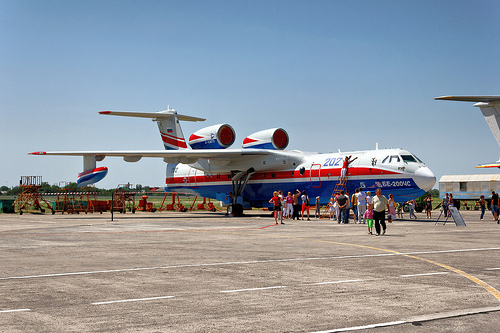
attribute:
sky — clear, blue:
[22, 70, 112, 102]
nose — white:
[412, 165, 434, 192]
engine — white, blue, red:
[188, 124, 237, 150]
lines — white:
[72, 212, 417, 332]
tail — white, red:
[94, 105, 209, 154]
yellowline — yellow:
[304, 236, 499, 327]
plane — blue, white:
[43, 87, 455, 227]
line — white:
[223, 285, 283, 295]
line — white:
[313, 275, 370, 287]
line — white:
[400, 267, 447, 277]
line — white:
[91, 292, 171, 304]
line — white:
[0, 306, 30, 315]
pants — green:
[360, 207, 399, 239]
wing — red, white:
[98, 109, 173, 119]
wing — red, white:
[176, 113, 205, 123]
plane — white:
[31, 102, 454, 251]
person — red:
[268, 182, 292, 224]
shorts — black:
[272, 187, 280, 254]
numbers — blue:
[321, 136, 348, 207]